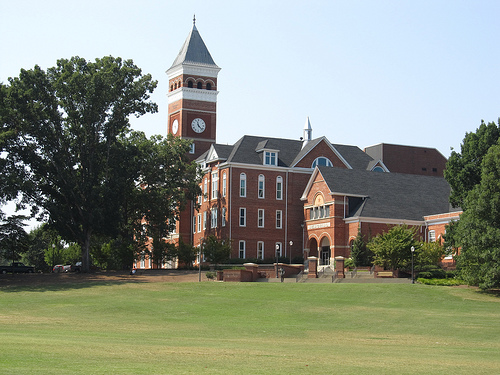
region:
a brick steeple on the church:
[165, 14, 220, 141]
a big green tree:
[1, 59, 206, 271]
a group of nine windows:
[238, 174, 284, 263]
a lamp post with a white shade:
[407, 246, 417, 284]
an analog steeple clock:
[190, 117, 206, 137]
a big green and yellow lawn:
[0, 284, 497, 374]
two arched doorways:
[304, 233, 333, 270]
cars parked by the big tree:
[3, 261, 83, 277]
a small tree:
[364, 223, 415, 274]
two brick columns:
[304, 254, 348, 280]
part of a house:
[348, 184, 365, 208]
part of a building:
[426, 247, 436, 272]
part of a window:
[267, 220, 275, 239]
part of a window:
[276, 211, 283, 223]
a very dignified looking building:
[63, 4, 483, 309]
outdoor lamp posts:
[259, 233, 298, 283]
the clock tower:
[166, 10, 228, 163]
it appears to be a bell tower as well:
[173, 65, 226, 100]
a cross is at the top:
[185, 4, 207, 36]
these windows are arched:
[235, 166, 289, 206]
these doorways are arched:
[295, 229, 340, 269]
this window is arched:
[308, 153, 336, 171]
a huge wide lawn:
[131, 286, 470, 366]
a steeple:
[299, 106, 314, 152]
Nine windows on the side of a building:
[235, 167, 287, 263]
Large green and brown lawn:
[1, 270, 499, 373]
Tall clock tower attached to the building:
[159, 5, 224, 157]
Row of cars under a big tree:
[1, 259, 94, 274]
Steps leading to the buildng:
[256, 256, 426, 288]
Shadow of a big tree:
[0, 265, 152, 295]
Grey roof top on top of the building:
[305, 161, 477, 222]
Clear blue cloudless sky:
[0, 65, 498, 156]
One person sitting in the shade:
[128, 263, 138, 276]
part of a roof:
[303, 172, 314, 174]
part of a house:
[267, 195, 283, 229]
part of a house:
[260, 188, 265, 211]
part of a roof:
[346, 201, 354, 226]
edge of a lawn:
[296, 251, 316, 300]